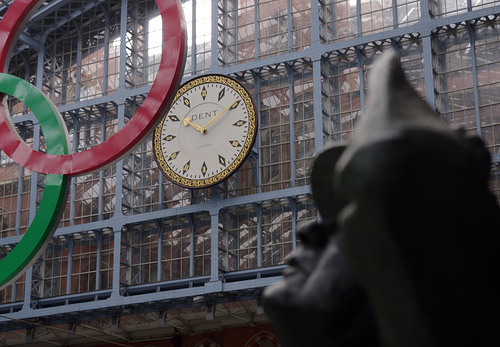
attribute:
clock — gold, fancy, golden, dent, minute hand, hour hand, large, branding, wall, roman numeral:
[153, 80, 259, 188]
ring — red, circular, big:
[172, 18, 192, 53]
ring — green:
[29, 99, 67, 158]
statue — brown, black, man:
[310, 94, 427, 268]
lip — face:
[260, 240, 314, 277]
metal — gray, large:
[304, 34, 325, 106]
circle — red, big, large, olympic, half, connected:
[5, 13, 196, 188]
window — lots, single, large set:
[218, 12, 305, 63]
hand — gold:
[182, 118, 208, 129]